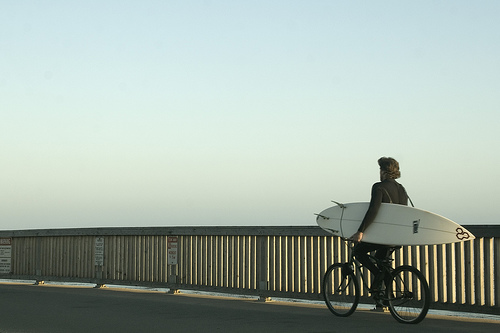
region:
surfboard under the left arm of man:
[307, 196, 477, 256]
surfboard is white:
[308, 193, 483, 255]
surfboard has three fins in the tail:
[309, 199, 350, 239]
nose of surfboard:
[449, 225, 479, 248]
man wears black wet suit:
[353, 146, 424, 324]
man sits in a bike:
[349, 149, 422, 314]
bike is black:
[308, 253, 439, 330]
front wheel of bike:
[314, 256, 364, 322]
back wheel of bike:
[379, 259, 439, 331]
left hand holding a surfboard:
[340, 184, 385, 251]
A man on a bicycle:
[310, 145, 414, 323]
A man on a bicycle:
[238, 120, 369, 325]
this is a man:
[336, 157, 424, 272]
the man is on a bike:
[332, 177, 402, 314]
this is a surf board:
[391, 212, 422, 241]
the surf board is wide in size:
[377, 212, 427, 241]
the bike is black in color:
[335, 270, 412, 312]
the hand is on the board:
[350, 205, 385, 245]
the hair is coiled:
[383, 160, 398, 176]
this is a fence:
[215, 231, 299, 283]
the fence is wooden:
[216, 227, 288, 291]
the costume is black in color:
[378, 183, 398, 198]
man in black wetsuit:
[355, 139, 407, 312]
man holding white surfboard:
[306, 139, 483, 260]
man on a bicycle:
[302, 134, 436, 321]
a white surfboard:
[311, 197, 473, 251]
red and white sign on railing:
[162, 232, 184, 277]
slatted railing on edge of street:
[3, 224, 320, 304]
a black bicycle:
[320, 249, 445, 324]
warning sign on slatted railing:
[0, 235, 24, 287]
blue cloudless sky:
[38, 22, 319, 119]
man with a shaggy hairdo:
[340, 147, 413, 265]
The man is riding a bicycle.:
[295, 140, 465, 325]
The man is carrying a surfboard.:
[300, 192, 481, 254]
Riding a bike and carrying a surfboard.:
[300, 130, 477, 320]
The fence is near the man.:
[10, 212, 492, 299]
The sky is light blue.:
[35, 15, 490, 125]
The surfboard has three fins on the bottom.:
[300, 185, 350, 240]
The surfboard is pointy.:
[436, 200, 478, 256]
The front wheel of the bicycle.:
[307, 252, 358, 322]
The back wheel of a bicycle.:
[380, 260, 430, 325]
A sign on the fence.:
[161, 235, 181, 270]